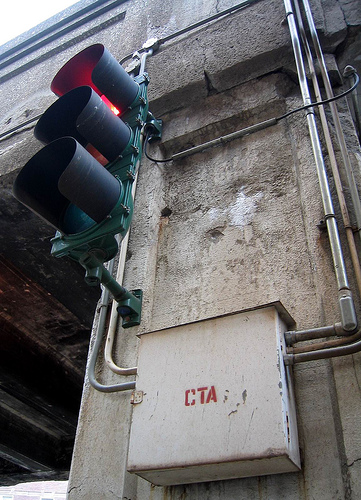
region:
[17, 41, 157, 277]
a green three way stop signal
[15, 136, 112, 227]
a green go stop signal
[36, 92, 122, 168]
a yellow yield signal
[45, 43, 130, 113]
a lit red stop signal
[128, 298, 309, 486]
a white box labeled CTA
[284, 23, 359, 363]
electric wire metal tubing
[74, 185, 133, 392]
electric wire metal tubing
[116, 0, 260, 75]
electric wire metal tubing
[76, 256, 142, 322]
a green structural support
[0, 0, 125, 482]
a bridge overpass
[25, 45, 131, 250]
3 lights in a row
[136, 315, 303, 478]
metal fuse box on building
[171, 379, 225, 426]
cta in red on box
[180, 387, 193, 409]
letter c on box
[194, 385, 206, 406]
letter t on box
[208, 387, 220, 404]
letter a on box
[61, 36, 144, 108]
red light on top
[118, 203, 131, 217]
bolt on side of light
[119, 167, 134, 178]
bolt on side of light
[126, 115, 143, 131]
bolt on side of light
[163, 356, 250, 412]
The wire "CTA" written on the box.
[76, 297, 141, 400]
Pipes running from the electrical box.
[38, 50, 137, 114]
The traffic light is on red.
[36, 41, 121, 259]
A traffic light attached to the wall.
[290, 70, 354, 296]
Long rods attached to the building.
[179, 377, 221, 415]
The letters on the electrical box is red.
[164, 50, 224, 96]
The cracks on the building.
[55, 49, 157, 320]
The traffic sign is green and black.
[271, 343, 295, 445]
Paint is peeling from the box on the side.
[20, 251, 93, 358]
The ceiling of the building is rusty.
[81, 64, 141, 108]
lit up red stop light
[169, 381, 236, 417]
white metal box that says cta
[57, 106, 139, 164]
orange light in the middle of three lights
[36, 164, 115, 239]
non-lit green street light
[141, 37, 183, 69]
metal silver junction box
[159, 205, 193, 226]
dark circular hole in concrete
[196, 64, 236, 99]
triangular crack in concrete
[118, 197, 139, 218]
metal screw to the right of the green light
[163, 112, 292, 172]
circular tube around wire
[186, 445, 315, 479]
rusty line on metal box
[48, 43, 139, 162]
stoplight showing red.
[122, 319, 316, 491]
white box with red writing.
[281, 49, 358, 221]
pipes on the wall.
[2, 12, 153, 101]
wall above the lights.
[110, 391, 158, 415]
hinge on the box.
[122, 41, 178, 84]
power junctions on the wall.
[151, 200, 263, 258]
holes in the wall.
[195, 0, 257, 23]
Crack in the wall.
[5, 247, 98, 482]
wood on the bottom side of the bridge.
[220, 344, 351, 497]
lines in the wall.